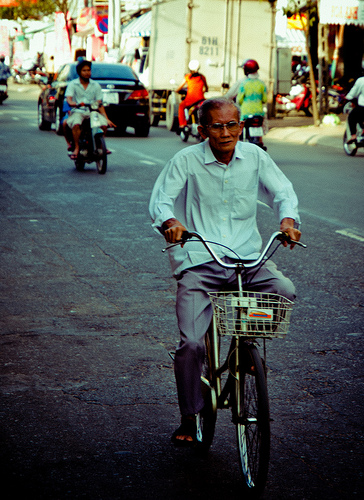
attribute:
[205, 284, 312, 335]
basket — wire, silver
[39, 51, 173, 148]
car — black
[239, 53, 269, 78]
helmet — colorful, white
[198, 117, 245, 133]
glasses — silver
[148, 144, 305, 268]
shirt — colorful